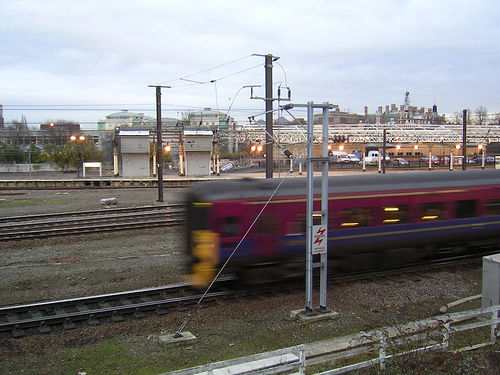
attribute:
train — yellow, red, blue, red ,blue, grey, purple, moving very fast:
[175, 167, 499, 288]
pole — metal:
[288, 101, 342, 322]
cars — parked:
[336, 147, 499, 168]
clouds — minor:
[41, 8, 305, 104]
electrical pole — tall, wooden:
[256, 48, 284, 177]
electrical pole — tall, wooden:
[146, 78, 174, 204]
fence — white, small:
[254, 304, 500, 374]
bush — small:
[364, 282, 484, 371]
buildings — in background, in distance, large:
[6, 88, 496, 160]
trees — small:
[24, 135, 103, 178]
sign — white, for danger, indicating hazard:
[311, 222, 328, 255]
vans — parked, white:
[332, 146, 363, 169]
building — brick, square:
[268, 121, 499, 166]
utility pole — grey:
[290, 96, 337, 314]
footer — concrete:
[291, 301, 339, 325]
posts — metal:
[302, 100, 333, 311]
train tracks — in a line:
[1, 200, 186, 236]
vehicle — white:
[365, 147, 387, 167]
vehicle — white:
[335, 151, 349, 166]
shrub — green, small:
[357, 282, 478, 373]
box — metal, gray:
[478, 251, 500, 320]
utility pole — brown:
[249, 50, 284, 179]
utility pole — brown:
[146, 82, 173, 203]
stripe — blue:
[279, 216, 500, 260]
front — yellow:
[174, 178, 221, 290]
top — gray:
[193, 166, 499, 200]